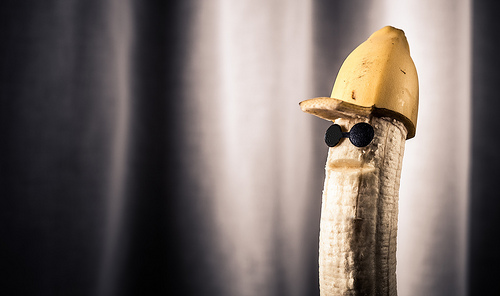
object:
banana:
[298, 25, 418, 296]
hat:
[297, 26, 425, 138]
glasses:
[321, 123, 373, 146]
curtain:
[0, 0, 470, 296]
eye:
[322, 126, 340, 147]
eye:
[347, 122, 381, 148]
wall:
[471, 0, 494, 295]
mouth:
[327, 160, 370, 174]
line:
[368, 121, 386, 277]